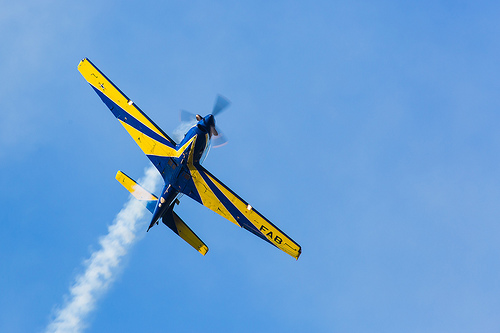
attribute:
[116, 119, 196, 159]
stripe — yellow 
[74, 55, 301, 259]
plane — blue and yellow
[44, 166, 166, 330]
clouds — white 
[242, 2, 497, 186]
clouds — white 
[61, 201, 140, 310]
clouds — white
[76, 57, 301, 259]
airplane — blue, yellow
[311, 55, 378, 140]
clouds — whtie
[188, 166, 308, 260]
stripe — yellow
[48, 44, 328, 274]
plane — blue and yellow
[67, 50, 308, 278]
airplane — blue and yellow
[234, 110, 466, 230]
clouds — white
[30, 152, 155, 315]
clouds — white 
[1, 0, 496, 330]
sky — blue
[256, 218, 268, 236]
letter — black 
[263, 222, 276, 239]
letter — black 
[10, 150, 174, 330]
clouds — white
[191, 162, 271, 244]
stripe — blue